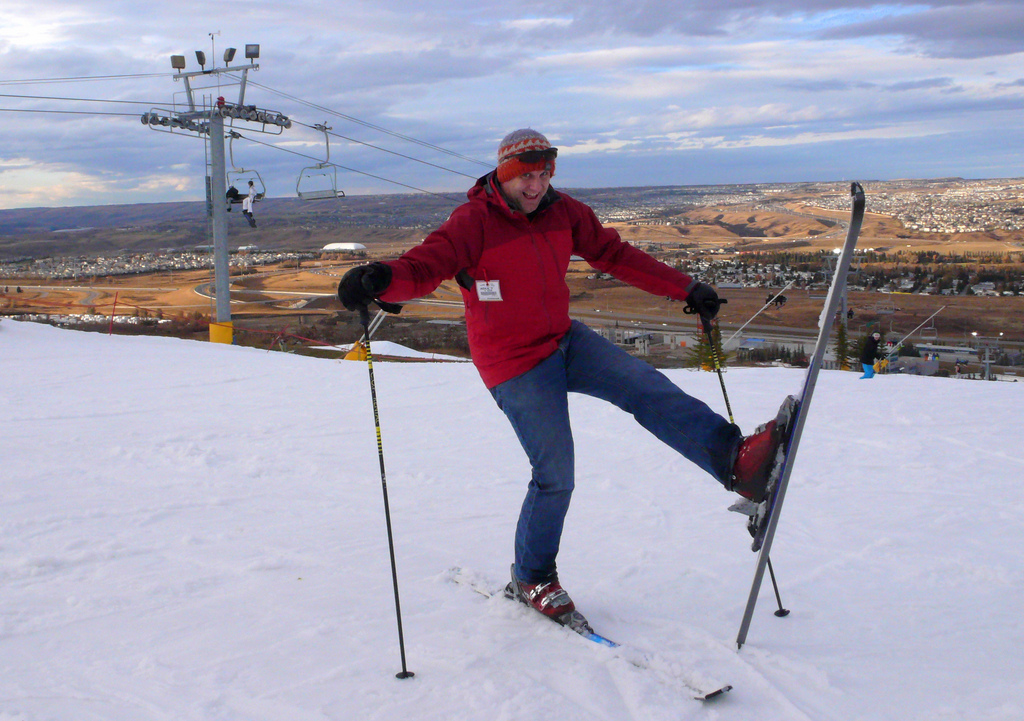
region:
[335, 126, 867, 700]
the boy is on a ski slope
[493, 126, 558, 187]
the knit hat is mostly red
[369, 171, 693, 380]
the man is wearing a red ski jacket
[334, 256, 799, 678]
ski poles are in the hands of the skier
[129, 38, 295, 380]
a ski lift tower is on the slope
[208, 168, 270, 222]
people are sitting in a quad lift chair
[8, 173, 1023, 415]
there is no snow in the lower town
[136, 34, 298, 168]
lights are on the top of the ski lift tower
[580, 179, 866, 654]
leg is attached to a ski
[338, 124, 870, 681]
man is holding ski poles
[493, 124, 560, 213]
man is wearing a beanie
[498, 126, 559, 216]
man is wearing sunglasses on his head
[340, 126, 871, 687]
man is wearing black gloves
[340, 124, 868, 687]
man is wearing red boots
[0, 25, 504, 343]
gondola is behind the man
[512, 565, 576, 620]
red boots have silver strapping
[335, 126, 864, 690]
man holding ski poles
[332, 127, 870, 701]
man wearing red coat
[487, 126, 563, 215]
man with mouth open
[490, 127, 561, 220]
man with sunglasses on head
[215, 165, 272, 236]
people sitting on ski lift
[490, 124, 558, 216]
man wearing red and grey hat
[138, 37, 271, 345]
lights on top of ski lift pole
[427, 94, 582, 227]
the head of a man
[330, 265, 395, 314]
the glove of a man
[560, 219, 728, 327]
the arm of a man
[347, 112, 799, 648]
a person is playing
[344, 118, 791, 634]
a person is standing up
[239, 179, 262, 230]
a person is sitting down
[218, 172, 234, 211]
a person is sitting down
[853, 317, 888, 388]
a person is standing up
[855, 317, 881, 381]
a person is playing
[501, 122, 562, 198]
a red ski cap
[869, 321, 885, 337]
a red ski cap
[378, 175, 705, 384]
a red ski jacket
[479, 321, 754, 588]
some blue pants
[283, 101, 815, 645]
man doing trick in snow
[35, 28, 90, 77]
white clouds in blue sky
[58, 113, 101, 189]
white clouds in blue sky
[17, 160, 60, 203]
white clouds in blue sky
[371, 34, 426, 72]
white clouds in blue sky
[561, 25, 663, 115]
white clouds in blue sky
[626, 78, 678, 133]
white clouds in blue sky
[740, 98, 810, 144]
white clouds in blue sky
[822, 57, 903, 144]
white clouds in blue sky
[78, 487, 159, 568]
snow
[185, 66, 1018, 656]
person with skis in the background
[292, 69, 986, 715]
person standing on the snow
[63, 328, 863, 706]
snow on the ground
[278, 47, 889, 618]
person wearing a red coat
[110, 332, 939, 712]
foot prints on the snow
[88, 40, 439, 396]
electric cables inn the background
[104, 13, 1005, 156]
a dark sky in the background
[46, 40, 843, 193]
clouds in the sky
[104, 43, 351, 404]
an electric pole in the background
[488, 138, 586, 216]
the head of a man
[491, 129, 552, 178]
the hat of a man